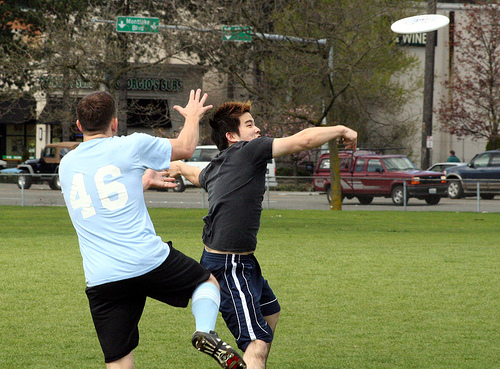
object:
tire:
[16, 172, 31, 190]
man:
[55, 83, 235, 367]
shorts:
[85, 245, 217, 360]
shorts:
[198, 248, 281, 350]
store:
[102, 62, 209, 167]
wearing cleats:
[188, 330, 250, 368]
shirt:
[50, 132, 174, 282]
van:
[167, 142, 273, 197]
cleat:
[188, 331, 244, 367]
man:
[156, 97, 366, 368]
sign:
[116, 16, 160, 34]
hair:
[207, 98, 252, 147]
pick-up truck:
[311, 149, 450, 205]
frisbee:
[389, 12, 449, 34]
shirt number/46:
[69, 163, 128, 220]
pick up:
[314, 146, 453, 204]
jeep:
[14, 140, 76, 187]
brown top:
[41, 137, 81, 163]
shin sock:
[188, 277, 228, 337]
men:
[50, 80, 367, 367]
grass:
[0, 205, 499, 369]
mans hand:
[173, 87, 213, 118]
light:
[440, 176, 446, 184]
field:
[0, 203, 500, 368]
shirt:
[195, 133, 274, 256]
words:
[34, 69, 188, 99]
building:
[22, 64, 210, 165]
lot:
[262, 152, 498, 209]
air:
[60, 7, 467, 67]